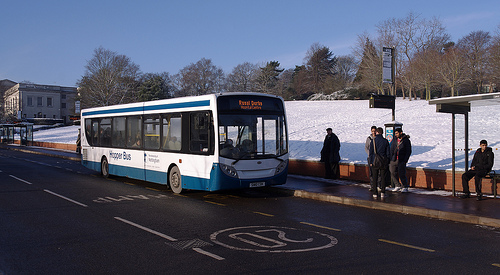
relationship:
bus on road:
[80, 91, 290, 195] [4, 149, 495, 273]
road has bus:
[4, 149, 495, 273] [80, 91, 290, 195]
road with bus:
[4, 149, 495, 273] [80, 91, 290, 195]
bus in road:
[80, 91, 290, 195] [4, 149, 495, 273]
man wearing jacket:
[387, 122, 412, 195] [387, 135, 411, 162]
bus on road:
[80, 91, 290, 195] [86, 75, 477, 258]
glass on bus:
[220, 114, 287, 159] [80, 91, 290, 195]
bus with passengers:
[19, 44, 335, 245] [251, 98, 470, 220]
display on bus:
[238, 100, 264, 110] [80, 91, 290, 195]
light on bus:
[270, 159, 288, 174] [80, 91, 290, 195]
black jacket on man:
[468, 147, 497, 182] [461, 134, 499, 196]